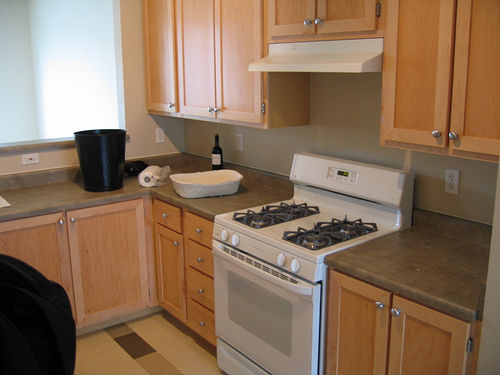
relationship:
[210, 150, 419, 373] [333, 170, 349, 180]
gas range with led display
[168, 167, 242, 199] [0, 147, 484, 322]
container on counter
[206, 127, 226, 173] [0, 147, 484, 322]
bottle on counter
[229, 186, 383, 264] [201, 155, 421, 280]
burners on stove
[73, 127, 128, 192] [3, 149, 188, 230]
bucket on sink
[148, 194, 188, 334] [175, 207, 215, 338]
cabinet and drawers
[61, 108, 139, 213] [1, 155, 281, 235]
bucket on top of sink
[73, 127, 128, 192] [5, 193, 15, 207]
bucket on sink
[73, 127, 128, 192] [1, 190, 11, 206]
bucket on sink